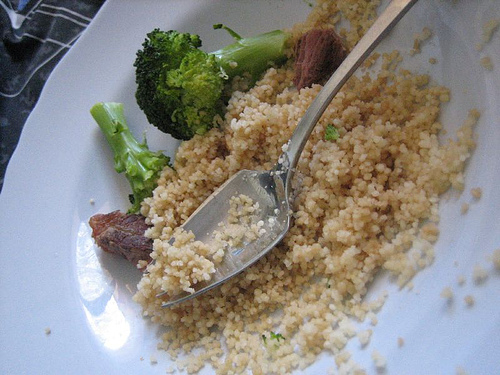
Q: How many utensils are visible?
A: One.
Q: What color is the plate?
A: White.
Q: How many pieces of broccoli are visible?
A: Two.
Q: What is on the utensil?
A: Rice.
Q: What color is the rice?
A: Brown.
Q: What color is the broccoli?
A: Green.